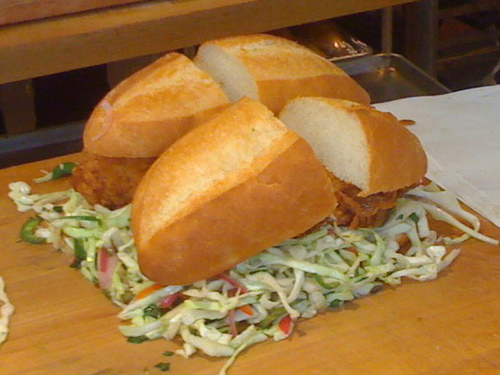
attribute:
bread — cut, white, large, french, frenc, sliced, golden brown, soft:
[107, 42, 399, 252]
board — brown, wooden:
[14, 158, 82, 340]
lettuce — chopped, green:
[58, 209, 139, 325]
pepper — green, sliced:
[19, 209, 52, 262]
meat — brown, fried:
[51, 145, 132, 232]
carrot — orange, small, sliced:
[237, 299, 266, 325]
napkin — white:
[395, 97, 500, 224]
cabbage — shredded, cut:
[298, 236, 408, 301]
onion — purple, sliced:
[221, 272, 258, 298]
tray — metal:
[347, 50, 442, 110]